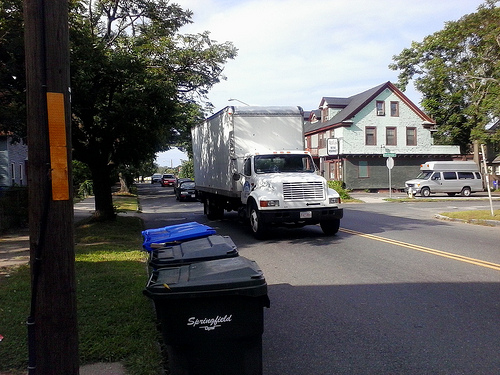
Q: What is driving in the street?
A: A truck.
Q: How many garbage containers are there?
A: Three.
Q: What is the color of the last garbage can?
A: Blue.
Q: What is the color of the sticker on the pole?
A: Orange.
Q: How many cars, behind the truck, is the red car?
A: 2.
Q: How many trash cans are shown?
A: 3.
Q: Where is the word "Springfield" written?
A: On the side of the trash can.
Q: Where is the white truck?
A: On the road.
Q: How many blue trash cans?
A: 1.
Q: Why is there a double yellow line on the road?
A: To prevent passing.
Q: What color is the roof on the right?
A: Reddish brown.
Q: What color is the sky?
A: Light blue.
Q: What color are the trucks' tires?
A: Black.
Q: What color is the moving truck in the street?
A: White.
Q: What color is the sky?
A: Blue.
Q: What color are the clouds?
A: White.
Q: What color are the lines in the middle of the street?
A: Yellow.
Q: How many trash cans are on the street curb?
A: Three.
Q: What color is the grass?
A: Green.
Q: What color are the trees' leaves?
A: Green.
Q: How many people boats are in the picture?
A: Zero.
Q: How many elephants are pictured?
A: Zero.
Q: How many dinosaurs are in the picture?
A: Zero.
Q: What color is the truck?
A: White.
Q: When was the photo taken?
A: Daytime.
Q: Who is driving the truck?
A: A driver.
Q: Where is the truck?
A: On the street.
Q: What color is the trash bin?
A: Black.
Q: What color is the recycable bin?
A: Blue.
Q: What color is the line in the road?
A: Yellow.